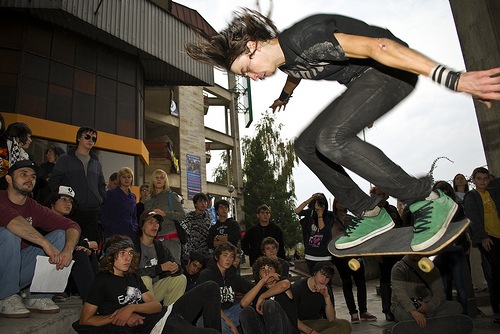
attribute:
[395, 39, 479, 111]
bracelets — white and black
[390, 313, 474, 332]
skateboard — black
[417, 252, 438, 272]
wheels — yellow 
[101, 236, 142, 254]
band — blue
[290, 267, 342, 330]
boy — three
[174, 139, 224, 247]
poster — blue and purple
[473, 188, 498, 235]
shirt — yellow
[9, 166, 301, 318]
people — group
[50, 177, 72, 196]
hat — black and white, trucker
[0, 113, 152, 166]
accent — orange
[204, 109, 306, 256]
tree — green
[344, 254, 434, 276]
wheels — yellow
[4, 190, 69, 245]
shirt — red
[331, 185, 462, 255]
shoes — green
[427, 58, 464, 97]
wrist bands — white and black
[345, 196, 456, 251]
shoes — green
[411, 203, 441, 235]
laces — black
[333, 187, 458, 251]
shoes — Green 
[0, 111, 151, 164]
bar — yellow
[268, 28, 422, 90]
shirt — black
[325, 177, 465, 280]
shoes — green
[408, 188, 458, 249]
shoe — green and white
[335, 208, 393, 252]
shoe — green and white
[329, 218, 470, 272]
skateboard — black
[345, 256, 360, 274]
wheel — yellow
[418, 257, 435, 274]
wheel — yellow